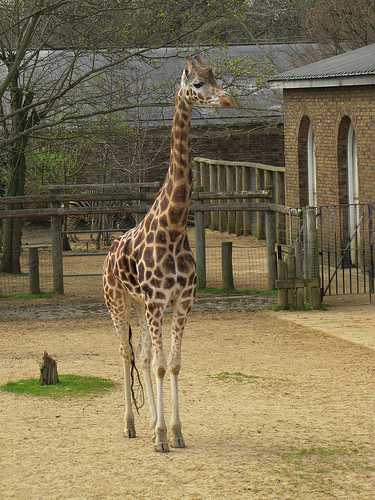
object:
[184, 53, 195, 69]
horn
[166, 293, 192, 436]
leg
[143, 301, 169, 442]
leg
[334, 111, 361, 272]
arch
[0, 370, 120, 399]
grass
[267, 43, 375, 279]
building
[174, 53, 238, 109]
head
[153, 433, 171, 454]
hoof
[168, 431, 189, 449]
hoof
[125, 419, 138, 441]
hoof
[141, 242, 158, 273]
spots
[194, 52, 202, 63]
horns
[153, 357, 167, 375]
knees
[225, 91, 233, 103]
nose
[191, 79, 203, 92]
eye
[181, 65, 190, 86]
ear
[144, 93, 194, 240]
neck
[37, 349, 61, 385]
wood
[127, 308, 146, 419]
tail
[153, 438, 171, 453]
feet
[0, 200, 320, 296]
wood fence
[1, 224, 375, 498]
ground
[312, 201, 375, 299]
gate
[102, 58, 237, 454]
giraffe